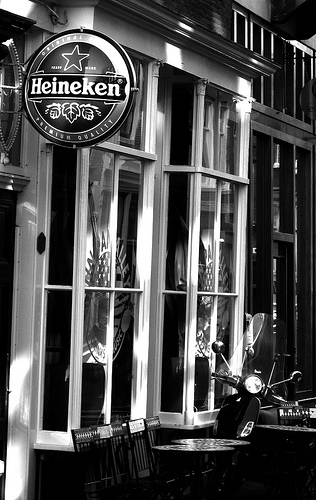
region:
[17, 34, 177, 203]
Heineken store front sign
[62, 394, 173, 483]
a pair of black bences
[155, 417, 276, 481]
two round breakfast tables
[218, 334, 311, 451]
a black moped parked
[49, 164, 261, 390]
a pair of bay windows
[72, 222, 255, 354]
two Heineken logo signs in window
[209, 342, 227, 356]
rearview mirrors of moped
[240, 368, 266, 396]
front head light of moped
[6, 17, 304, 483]
black and white photo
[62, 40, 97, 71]
white and black logo star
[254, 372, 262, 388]
head light of a bike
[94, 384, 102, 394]
part of a window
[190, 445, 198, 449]
part of a table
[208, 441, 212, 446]
top of a table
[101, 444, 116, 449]
back rest of a seat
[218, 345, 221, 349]
mirror of a bike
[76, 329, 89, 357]
a white window pane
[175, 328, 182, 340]
section of a window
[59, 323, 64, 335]
part of a window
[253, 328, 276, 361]
window of a bike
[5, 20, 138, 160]
Beer sign in front of restaurant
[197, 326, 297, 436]
Motorbike in front of restaurant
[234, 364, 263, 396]
Headlight on motorbike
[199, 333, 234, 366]
Rearview mirror on motorbike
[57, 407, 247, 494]
Table and chairs in front of restaurant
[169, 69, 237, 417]
Window on front of restaurant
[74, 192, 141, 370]
Sign in the front of restaurant window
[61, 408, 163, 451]
Chair backs in front of restaurant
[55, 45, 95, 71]
Star on a sign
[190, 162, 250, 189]
Wood trim on window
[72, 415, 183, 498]
Chairs outside of building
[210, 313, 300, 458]
Motorcycle leaned against building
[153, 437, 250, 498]
Small round tables together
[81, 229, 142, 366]
Logo in window pane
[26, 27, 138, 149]
Heineken building sign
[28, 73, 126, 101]
Word HEINEKEN in black and white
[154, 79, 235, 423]
Front window pane of building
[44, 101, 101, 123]
Drawing of hops in black and white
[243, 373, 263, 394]
motorcycle head light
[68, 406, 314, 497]
Outside dining area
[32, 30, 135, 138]
black and white sign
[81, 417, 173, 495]
chairs next to table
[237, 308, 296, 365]
front screen on the motorcycle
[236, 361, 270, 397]
light on front of bike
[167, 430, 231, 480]
two circular tables on ground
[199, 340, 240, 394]
handlebar on the bike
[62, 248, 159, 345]
windows of a place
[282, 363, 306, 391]
rearview mirror on bike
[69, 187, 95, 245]
white part of window